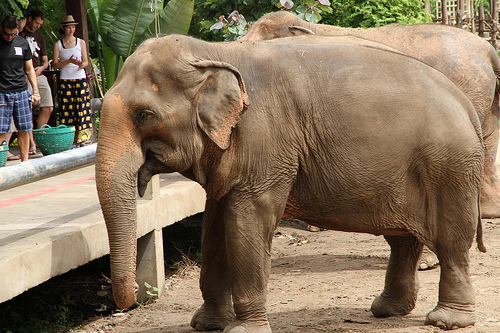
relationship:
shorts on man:
[26, 73, 57, 112] [23, 10, 54, 133]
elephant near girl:
[97, 33, 479, 328] [51, 14, 93, 147]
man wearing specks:
[2, 14, 30, 161] [4, 29, 19, 39]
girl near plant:
[51, 14, 93, 147] [79, 3, 193, 130]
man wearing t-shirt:
[2, 14, 30, 161] [1, 32, 31, 92]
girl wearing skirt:
[94, 20, 95, 147] [93, 81, 105, 130]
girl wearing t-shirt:
[94, 20, 95, 147] [93, 41, 101, 83]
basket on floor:
[34, 122, 76, 154] [8, 116, 235, 255]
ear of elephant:
[193, 61, 249, 152] [97, 33, 479, 328]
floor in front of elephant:
[9, 176, 482, 327] [97, 33, 479, 328]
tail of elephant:
[478, 137, 488, 260] [97, 33, 479, 328]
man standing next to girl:
[27, 10, 54, 125] [51, 14, 93, 147]